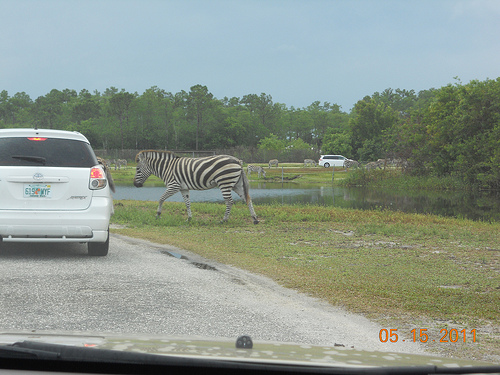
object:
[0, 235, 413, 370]
road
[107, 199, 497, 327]
grass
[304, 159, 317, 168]
animal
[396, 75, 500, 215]
tree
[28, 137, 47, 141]
light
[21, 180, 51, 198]
plates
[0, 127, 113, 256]
car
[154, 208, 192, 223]
feet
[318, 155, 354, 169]
car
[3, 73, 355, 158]
trees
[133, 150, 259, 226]
zebra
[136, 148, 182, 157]
mane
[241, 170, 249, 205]
tail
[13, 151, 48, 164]
windshield wiper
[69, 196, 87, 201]
writing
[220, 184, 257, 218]
legs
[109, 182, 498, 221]
lake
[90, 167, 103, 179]
brake light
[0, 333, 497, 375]
car hood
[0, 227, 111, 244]
car bumper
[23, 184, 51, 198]
license plate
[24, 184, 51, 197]
writing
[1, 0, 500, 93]
sky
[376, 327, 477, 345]
date